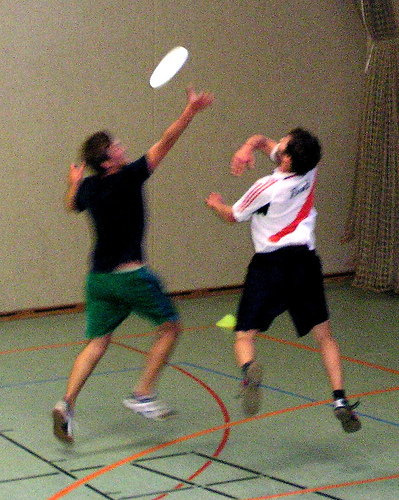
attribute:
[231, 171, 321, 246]
shirt — white , red 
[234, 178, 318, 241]
shirt — white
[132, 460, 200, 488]
line — black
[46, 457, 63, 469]
line — black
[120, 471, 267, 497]
line — black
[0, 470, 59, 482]
line — black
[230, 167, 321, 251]
shirt — White 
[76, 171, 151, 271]
shirt — black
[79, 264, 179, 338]
shorts — green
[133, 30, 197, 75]
frisbee — white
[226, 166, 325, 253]
shirt — White 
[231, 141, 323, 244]
shirt — White 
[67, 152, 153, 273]
shirt — black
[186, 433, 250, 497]
line — black 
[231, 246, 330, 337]
shorts — black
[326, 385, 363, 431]
shoe — white , black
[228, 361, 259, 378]
sock — black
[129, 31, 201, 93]
frisbee — white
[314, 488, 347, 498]
line — black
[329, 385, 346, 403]
sock — black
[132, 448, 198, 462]
line — black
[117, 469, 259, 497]
line — black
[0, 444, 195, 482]
line — black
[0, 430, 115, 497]
line — black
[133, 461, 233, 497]
line — black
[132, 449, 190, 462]
line — black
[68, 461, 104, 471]
line — black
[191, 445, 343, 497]
line — black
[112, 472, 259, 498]
line — black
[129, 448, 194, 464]
line — black